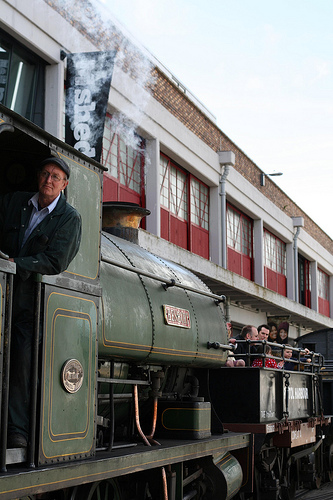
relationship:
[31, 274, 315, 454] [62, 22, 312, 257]
train at station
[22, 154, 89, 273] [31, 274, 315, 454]
driver on train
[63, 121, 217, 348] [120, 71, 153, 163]
locomotive have steam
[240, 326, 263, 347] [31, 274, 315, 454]
man on train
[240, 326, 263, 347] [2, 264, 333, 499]
man enjoying train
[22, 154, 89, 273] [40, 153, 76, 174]
driver have hat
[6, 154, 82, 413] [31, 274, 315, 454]
driver on train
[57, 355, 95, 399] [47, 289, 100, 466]
attachment on door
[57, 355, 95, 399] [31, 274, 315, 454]
attachment on train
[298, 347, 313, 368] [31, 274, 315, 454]
boy on train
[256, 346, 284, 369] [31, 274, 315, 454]
girl on train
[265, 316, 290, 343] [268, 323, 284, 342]
banner has people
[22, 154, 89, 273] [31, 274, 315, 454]
guide on train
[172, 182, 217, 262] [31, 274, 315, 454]
windows on train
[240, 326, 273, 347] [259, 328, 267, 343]
man has head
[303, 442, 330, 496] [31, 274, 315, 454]
wheel on train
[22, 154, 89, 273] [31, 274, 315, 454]
captain on train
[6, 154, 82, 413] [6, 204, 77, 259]
driver wearing jacket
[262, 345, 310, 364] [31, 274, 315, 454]
children on train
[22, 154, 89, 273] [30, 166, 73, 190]
driver wearing glasses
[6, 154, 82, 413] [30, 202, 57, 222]
driver wearing shirt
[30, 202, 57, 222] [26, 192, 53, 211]
shirt has collar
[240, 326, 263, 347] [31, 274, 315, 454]
man riding train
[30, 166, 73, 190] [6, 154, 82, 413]
glasses on driver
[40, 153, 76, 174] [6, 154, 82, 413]
hat on driver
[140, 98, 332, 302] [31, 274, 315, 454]
building behind train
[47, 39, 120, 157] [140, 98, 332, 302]
sign on building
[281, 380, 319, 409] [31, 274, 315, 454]
sign on train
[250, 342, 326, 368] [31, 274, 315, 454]
railing on train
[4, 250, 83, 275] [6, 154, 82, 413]
arm on driver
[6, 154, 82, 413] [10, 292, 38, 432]
driver has leg